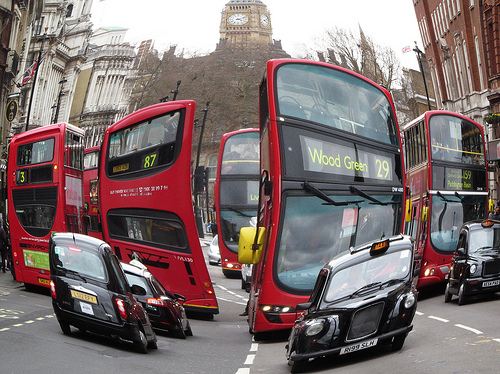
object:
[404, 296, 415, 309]
light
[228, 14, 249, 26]
clock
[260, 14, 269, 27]
clock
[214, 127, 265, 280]
bus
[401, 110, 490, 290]
bus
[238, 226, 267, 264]
mirror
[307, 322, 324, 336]
light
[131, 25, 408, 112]
tree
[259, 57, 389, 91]
roof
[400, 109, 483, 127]
roof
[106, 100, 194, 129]
roof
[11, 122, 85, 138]
roof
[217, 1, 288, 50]
building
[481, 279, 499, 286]
license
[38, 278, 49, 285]
license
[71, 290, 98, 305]
license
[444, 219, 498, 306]
car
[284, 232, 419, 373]
car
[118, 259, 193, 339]
car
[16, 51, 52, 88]
flag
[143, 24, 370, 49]
tree tops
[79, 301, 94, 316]
license plate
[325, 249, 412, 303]
window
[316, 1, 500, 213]
building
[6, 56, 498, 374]
buses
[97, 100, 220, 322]
bus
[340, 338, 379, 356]
license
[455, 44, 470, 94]
window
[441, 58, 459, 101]
window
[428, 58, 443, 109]
window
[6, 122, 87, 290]
bus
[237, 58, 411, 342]
bus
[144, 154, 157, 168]
87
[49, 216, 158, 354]
car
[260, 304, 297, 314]
headlight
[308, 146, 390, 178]
bus number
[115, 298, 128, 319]
light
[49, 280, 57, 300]
light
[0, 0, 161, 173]
building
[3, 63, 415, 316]
front panels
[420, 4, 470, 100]
trim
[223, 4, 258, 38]
panels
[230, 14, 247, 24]
numbers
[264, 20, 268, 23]
hands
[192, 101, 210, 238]
pole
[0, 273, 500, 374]
road